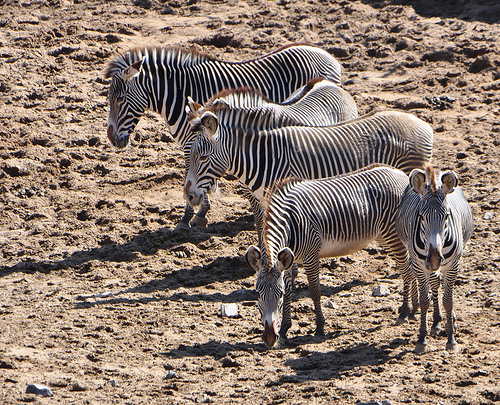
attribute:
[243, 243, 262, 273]
ear — facing forward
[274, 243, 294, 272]
ear — facing forward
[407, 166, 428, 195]
ear — facing forward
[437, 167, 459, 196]
ear — facing forward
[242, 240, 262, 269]
ear — sticking up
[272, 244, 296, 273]
ear — sticking up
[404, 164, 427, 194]
ear — sticking up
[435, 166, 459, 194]
ear — sticking up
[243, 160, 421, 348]
zebra — eating, black, white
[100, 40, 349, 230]
zebra — black, white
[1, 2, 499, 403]
bare ground — dirt, brown, rough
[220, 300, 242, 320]
rock — grey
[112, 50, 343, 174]
stripes — black, white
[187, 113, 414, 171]
stripes — black, white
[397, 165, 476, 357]
zebra — facing forward, black, white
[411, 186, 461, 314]
stripes — bla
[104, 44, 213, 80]
mane — striped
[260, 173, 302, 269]
mane — striped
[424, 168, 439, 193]
mane — striped